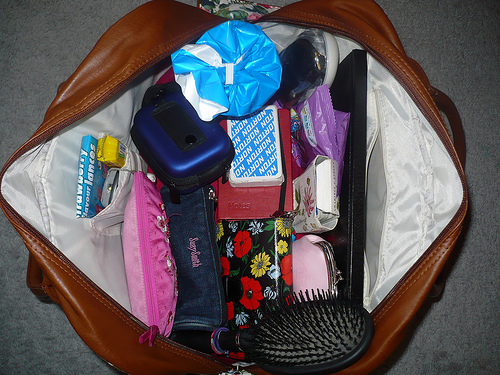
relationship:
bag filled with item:
[7, 4, 475, 372] [168, 15, 287, 124]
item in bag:
[168, 15, 287, 124] [7, 4, 475, 372]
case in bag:
[133, 103, 231, 185] [27, 29, 462, 369]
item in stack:
[168, 15, 287, 124] [227, 104, 286, 190]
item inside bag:
[168, 15, 287, 124] [7, 4, 475, 372]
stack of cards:
[227, 105, 281, 187] [225, 104, 286, 188]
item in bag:
[168, 15, 287, 124] [0, 0, 474, 375]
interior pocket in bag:
[76, 135, 146, 233] [0, 0, 474, 375]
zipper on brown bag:
[358, 27, 472, 345] [2, 24, 487, 366]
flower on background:
[251, 252, 273, 276] [221, 209, 285, 325]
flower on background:
[231, 229, 251, 256] [221, 209, 285, 325]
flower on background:
[237, 276, 264, 306] [221, 209, 285, 325]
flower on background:
[274, 236, 288, 255] [221, 209, 285, 325]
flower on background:
[221, 255, 229, 274] [221, 209, 285, 325]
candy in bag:
[91, 133, 140, 172] [0, 0, 474, 375]